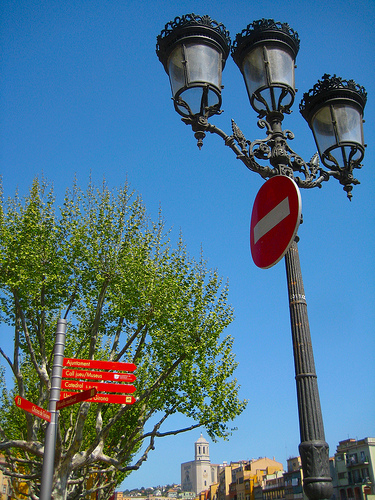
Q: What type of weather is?
A: It is clear.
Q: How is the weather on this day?
A: It is clear.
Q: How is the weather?
A: It is clear.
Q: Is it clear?
A: Yes, it is clear.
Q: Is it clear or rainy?
A: It is clear.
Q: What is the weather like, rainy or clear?
A: It is clear.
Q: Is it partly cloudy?
A: No, it is clear.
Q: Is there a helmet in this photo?
A: No, there are no helmets.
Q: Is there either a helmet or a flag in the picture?
A: No, there are no helmets or flags.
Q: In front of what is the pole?
A: The pole is in front of the buildings.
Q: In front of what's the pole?
A: The pole is in front of the buildings.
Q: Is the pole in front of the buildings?
A: Yes, the pole is in front of the buildings.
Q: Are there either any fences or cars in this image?
A: No, there are no cars or fences.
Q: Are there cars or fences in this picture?
A: No, there are no cars or fences.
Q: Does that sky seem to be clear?
A: Yes, the sky is clear.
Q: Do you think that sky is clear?
A: Yes, the sky is clear.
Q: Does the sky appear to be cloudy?
A: No, the sky is clear.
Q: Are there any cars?
A: No, there are no cars.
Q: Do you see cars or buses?
A: No, there are no cars or buses.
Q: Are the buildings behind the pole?
A: Yes, the buildings are behind the pole.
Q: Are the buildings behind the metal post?
A: Yes, the buildings are behind the post.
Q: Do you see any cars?
A: No, there are no cars.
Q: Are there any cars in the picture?
A: No, there are no cars.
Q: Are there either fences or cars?
A: No, there are no cars or fences.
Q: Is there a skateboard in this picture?
A: No, there are no skateboards.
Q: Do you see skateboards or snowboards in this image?
A: No, there are no skateboards or snowboards.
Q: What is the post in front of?
A: The post is in front of the buildings.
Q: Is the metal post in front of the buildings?
A: Yes, the post is in front of the buildings.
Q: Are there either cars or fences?
A: No, there are no cars or fences.